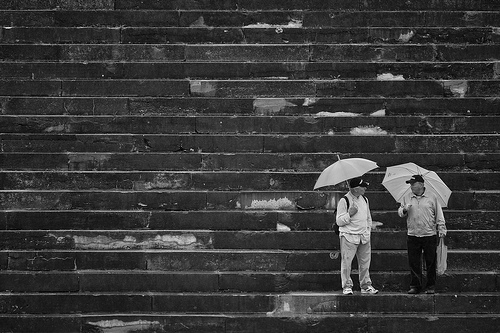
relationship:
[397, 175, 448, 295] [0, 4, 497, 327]
man talking on staircase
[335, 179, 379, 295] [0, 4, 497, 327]
man talking on staircase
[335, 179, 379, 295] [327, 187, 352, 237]
man wearing backpack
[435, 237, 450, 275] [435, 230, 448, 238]
bag in hand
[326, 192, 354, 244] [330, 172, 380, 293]
backpack on man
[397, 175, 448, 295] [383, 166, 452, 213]
man holding umbrella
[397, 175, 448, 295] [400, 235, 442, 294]
man wearing pants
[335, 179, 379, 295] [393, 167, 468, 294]
man talking to man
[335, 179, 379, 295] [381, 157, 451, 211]
man holding umbrella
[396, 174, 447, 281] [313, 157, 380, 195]
man holding umbrella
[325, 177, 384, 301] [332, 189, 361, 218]
man has shoulder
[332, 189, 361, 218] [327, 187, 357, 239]
shoulder has backpack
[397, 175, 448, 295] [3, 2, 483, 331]
man near wall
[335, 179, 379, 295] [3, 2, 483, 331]
man near wall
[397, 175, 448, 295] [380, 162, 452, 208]
man holding man's umbrella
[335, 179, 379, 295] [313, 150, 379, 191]
man holding umbrella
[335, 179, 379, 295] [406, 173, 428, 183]
man wearing ball cap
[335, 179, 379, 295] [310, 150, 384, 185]
man holding umbrella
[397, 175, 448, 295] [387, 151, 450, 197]
man holding umbrella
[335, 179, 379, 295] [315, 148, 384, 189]
man with umbrella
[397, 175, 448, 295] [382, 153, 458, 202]
man with umbrella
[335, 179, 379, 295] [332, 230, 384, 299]
man with jeans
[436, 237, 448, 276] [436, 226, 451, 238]
bag on hand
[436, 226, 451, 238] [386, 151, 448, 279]
hand on man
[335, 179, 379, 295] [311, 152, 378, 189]
man with umbrella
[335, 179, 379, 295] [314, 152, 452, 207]
man holding umbrellas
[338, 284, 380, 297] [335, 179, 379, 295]
shoes on man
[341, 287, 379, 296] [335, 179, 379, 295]
shoes on man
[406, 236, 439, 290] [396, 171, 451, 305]
pants on man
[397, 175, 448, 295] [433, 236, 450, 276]
man holding bag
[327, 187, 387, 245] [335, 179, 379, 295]
shirt on man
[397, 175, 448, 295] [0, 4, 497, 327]
man on staircase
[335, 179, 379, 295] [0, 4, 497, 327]
man on staircase